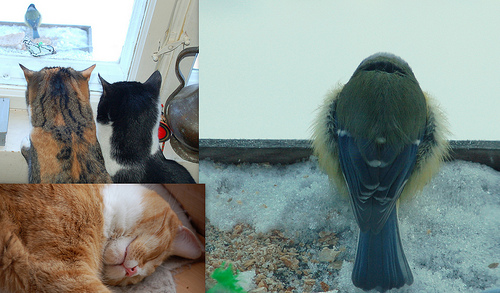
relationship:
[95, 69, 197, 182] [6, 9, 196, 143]
cat look out window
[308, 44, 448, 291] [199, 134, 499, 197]
bird on gutter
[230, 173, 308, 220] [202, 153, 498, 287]
snow on roof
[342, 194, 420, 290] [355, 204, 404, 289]
tail has feathers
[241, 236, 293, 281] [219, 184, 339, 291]
seeds on snow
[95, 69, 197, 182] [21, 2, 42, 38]
cat watch bird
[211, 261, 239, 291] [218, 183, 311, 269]
feather laying in snow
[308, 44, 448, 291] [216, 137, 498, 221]
bird on ground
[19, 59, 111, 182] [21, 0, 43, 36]
cat watching bird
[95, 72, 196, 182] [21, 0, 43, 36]
cat watching bird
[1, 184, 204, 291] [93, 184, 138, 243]
cat has patch